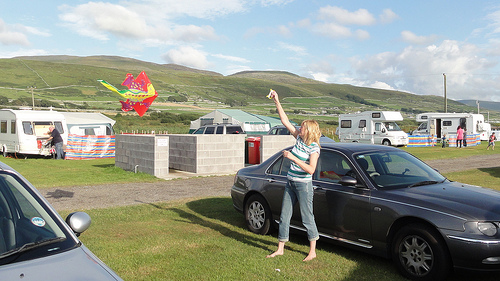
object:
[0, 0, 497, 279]
landscape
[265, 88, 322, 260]
lady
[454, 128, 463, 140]
shirt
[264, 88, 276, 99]
string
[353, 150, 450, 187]
windshield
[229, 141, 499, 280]
car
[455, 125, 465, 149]
woman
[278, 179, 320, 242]
pants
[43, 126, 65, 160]
man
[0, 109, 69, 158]
trailer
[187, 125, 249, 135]
trailer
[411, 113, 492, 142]
trailer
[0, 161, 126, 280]
car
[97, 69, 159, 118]
kite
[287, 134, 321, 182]
shirt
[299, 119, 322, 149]
hair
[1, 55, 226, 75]
mountain top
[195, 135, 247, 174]
wall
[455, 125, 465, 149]
people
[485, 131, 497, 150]
people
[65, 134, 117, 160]
fence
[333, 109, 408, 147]
campers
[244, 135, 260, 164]
bin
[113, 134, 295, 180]
structure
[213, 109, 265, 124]
roof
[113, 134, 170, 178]
barrier.